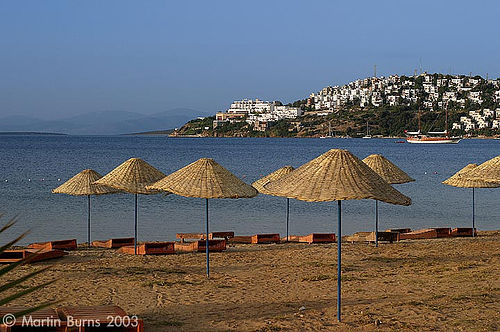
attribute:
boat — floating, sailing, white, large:
[404, 103, 463, 144]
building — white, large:
[227, 97, 301, 121]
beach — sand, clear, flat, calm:
[1, 227, 500, 332]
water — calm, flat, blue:
[1, 136, 500, 250]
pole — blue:
[335, 198, 343, 324]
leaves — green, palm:
[1, 209, 67, 332]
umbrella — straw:
[259, 146, 412, 206]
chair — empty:
[3, 247, 64, 263]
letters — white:
[20, 315, 102, 330]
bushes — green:
[380, 109, 455, 136]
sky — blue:
[1, 4, 499, 120]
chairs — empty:
[346, 225, 476, 241]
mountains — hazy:
[1, 105, 221, 135]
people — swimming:
[393, 140, 406, 144]